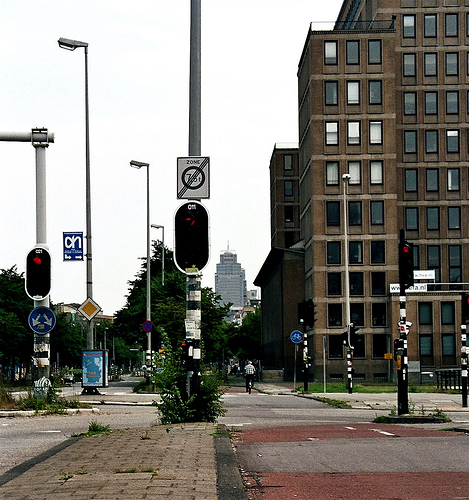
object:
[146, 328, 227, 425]
bush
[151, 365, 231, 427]
green plant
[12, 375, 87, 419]
green plant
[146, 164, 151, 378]
pole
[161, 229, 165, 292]
pole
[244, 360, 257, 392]
person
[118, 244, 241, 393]
tree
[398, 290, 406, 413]
post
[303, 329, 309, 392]
post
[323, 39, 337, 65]
window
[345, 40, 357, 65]
window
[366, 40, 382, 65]
window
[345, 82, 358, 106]
window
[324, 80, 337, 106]
window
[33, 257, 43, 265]
glowing red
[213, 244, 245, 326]
building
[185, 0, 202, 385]
pole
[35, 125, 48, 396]
pole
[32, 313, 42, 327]
arrows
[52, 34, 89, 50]
light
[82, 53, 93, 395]
post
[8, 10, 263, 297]
clouds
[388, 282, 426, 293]
sign board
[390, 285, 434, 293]
business name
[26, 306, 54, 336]
sign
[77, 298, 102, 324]
sign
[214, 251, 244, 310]
wall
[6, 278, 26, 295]
leaves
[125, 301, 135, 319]
leaves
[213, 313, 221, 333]
leaves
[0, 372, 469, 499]
road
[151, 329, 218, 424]
tree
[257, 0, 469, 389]
city building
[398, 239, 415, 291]
black signal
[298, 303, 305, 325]
black signal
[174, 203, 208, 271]
black signal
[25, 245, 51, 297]
black signal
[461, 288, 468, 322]
black signal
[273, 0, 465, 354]
wall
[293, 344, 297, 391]
pole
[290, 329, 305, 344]
sign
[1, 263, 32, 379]
tree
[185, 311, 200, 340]
poster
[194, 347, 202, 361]
poster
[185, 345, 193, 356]
poster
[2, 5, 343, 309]
sky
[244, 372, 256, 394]
bicycle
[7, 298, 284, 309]
horizon